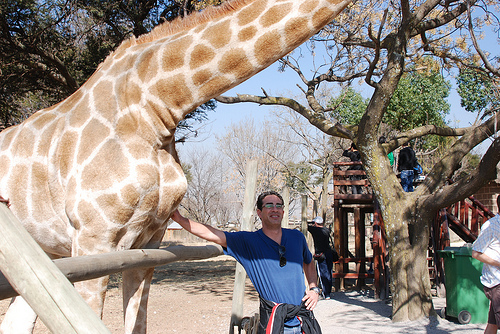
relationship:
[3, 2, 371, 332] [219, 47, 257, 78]
giraffe has spot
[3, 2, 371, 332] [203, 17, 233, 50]
giraffe has spot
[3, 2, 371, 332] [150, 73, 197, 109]
giraffe has spot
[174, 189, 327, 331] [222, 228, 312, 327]
man wearing jacket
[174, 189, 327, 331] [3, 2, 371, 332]
man touching giraffe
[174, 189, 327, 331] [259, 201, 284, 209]
man wearing glasses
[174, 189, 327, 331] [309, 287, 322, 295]
man wearing watch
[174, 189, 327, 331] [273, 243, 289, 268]
man has sunglasses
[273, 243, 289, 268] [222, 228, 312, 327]
sunglasses on jacket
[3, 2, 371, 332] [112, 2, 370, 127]
giraffe has neck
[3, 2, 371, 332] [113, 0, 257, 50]
giraffe has mane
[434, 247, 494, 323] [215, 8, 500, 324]
trash can under tree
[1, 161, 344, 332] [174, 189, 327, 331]
fence between man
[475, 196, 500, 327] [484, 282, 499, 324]
man wearing shorts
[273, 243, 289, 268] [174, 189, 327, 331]
sunglasses around man